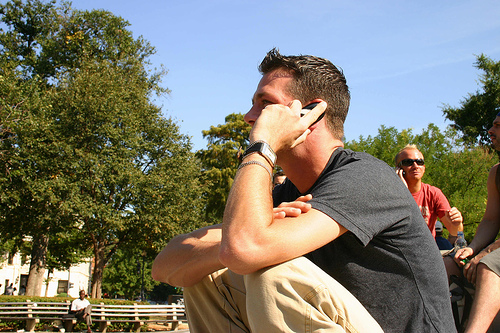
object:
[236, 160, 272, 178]
bracelet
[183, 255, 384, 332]
pants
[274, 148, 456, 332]
shirt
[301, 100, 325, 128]
phone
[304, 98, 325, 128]
ear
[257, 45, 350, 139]
hair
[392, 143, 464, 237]
man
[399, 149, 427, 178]
face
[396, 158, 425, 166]
sunglasses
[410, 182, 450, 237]
shirt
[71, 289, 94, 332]
person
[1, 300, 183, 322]
bench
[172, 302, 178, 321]
post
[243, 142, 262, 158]
band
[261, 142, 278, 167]
face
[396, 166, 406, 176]
phone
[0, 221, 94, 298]
building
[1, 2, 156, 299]
tree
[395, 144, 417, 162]
hair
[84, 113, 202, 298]
tree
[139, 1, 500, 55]
sky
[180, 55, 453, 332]
man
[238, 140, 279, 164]
watch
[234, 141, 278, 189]
wrist